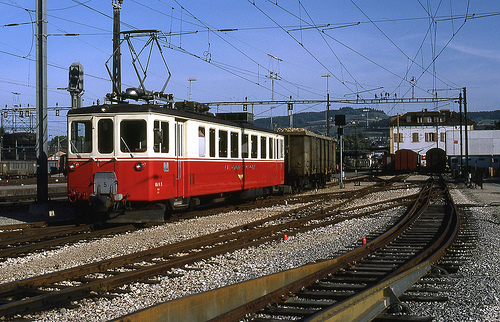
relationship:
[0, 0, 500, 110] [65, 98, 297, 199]
power lines strung above trolley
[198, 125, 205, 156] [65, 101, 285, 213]
window on trolley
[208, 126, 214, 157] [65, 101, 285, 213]
window on trolley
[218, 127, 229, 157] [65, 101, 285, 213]
window on trolley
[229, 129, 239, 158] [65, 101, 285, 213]
window on trolley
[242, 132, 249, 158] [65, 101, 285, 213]
window on trolley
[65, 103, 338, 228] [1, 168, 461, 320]
car on tracks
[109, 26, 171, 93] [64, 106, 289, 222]
black bar to trolley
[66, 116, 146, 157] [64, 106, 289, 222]
windows on trolley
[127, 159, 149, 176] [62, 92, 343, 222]
headlight of train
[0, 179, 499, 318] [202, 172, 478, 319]
gravel in track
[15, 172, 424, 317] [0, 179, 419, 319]
gravel in track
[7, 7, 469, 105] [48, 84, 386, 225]
structures above train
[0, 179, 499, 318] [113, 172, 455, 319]
gravel between tracks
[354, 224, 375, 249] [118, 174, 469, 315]
object on track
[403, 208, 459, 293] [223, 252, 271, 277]
tracks crisscrossing gravel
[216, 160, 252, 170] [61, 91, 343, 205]
writing on train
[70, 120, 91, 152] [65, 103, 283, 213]
window in train car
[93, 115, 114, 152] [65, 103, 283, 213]
window in train car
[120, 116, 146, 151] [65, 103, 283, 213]
window in train car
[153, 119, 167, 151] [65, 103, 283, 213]
window in train car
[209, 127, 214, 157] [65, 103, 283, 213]
window in train car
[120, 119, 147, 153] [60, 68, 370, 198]
window on trolley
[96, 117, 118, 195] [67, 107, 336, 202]
door of train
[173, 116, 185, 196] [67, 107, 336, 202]
door of train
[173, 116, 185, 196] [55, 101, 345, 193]
door of train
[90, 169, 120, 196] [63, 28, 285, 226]
grey front to trolley